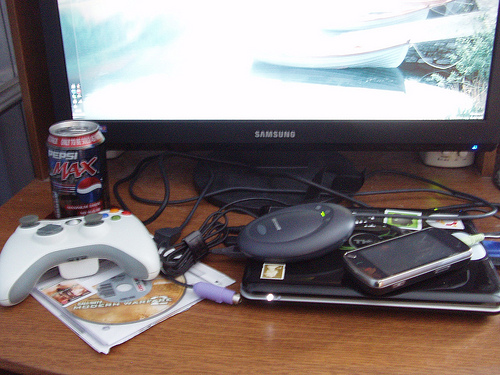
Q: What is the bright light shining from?
A: Monitor.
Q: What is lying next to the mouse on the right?
A: Cell Phone.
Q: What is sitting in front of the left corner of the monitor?
A: A soda can.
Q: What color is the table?
A: Brown.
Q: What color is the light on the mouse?
A: Green.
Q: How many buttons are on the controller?
A: Eight.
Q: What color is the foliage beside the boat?
A: Green.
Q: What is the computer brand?
A: Samsung.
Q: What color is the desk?
A: Brown.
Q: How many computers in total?
A: Two.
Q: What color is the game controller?
A: White and grey.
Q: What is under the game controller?
A: Discs.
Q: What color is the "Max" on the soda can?
A: Red.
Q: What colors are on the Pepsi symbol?
A: Red, white, and blue.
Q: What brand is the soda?
A: Pepsi Max.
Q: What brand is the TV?
A: Samsung.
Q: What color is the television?
A: Black.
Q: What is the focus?
A: Gaming.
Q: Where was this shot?
A: Desk.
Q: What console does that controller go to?
A: Xbox 360.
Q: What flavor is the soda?
A: Pepsi max.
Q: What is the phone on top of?
A: Netbook.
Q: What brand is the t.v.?
A: Samsung.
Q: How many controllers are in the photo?
A: 1.